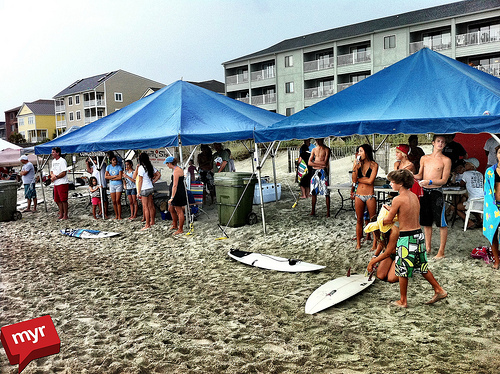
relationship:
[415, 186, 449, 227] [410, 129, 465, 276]
trunk on man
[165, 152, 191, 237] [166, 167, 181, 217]
woman in bathing suit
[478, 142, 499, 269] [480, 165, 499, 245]
person holding towel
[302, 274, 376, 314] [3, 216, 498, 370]
surfboard on sand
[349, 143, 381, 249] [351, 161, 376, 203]
woman in a bikini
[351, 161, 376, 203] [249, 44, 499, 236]
bikini standing by tent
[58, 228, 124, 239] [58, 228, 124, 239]
surfboard with surfboard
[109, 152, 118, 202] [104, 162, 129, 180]
girl in shirt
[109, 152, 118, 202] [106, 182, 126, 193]
girl in shorts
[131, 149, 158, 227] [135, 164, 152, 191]
girl in white shirt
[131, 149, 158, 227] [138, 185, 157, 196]
girl in gray shorts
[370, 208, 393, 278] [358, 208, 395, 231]
woman wearing hat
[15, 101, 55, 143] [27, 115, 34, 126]
house with window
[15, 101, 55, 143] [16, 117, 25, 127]
house with window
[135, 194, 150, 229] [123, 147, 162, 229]
leg of woman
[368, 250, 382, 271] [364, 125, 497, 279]
leg of woman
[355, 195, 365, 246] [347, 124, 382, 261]
leg of woman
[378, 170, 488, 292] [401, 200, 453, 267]
boy wearing trunks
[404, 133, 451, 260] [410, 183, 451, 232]
man wearing black trunks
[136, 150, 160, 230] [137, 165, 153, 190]
girl has white shirt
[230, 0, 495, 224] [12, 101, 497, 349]
building on beach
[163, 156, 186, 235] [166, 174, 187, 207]
woman in bathing suit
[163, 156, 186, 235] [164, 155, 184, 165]
woman in cap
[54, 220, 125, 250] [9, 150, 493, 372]
surfboard in sand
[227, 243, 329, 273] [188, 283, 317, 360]
white surfboard in sand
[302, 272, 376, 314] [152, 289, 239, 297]
surfboard in sand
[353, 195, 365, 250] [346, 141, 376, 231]
leg of woman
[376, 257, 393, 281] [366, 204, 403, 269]
leg is on woman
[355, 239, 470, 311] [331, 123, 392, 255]
leg is on woman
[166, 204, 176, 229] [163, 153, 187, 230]
leg is on woman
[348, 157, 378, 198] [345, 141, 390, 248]
suit is on woman